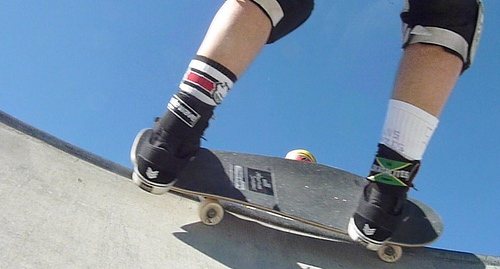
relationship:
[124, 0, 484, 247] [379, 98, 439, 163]
man wearing sock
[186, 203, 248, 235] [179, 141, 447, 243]
wheel on skateboard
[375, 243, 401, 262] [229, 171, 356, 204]
wheel are on skateboard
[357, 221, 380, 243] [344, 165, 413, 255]
logo on shoe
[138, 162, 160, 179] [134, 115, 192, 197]
logo on shoe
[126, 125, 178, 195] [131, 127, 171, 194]
shoe has sole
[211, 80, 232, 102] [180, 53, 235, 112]
logo on sock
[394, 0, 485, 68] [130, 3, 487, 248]
pad on skateboarder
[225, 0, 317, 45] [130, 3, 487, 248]
kneepads on skateboarder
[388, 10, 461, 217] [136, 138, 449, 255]
leg on skateboard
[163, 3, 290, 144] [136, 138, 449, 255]
leg on skateboard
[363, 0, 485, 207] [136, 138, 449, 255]
leg on skateboard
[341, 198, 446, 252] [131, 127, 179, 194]
shoe has sole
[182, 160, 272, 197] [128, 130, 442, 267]
label on skateboard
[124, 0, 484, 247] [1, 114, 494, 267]
man skateboarding on ramp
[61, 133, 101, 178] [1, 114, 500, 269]
metal edge on ramp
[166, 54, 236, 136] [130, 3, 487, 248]
sock on skateboarder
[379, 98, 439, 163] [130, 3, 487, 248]
sock on skateboarder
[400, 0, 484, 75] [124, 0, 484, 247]
pad on man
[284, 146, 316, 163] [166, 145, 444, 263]
object behind skateboard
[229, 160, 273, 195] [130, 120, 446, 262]
label on skateboard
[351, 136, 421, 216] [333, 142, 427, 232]
brace on ankle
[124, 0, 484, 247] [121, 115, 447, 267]
man raises board